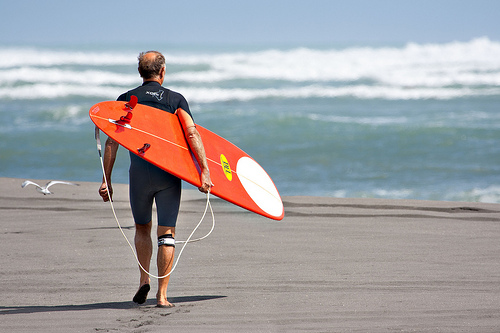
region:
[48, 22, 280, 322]
man carrying a surfboard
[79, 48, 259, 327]
man carrying a surfboard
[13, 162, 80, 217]
the bird is white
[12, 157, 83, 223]
the bird is white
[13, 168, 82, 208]
the bird is white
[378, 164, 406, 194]
Small ripples in the water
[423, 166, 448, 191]
Small ripples in the water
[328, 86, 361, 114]
Small ripples in the water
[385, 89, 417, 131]
Small ripples in the water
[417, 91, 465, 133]
Small ripples in the water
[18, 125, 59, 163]
Small ripples in the water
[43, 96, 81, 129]
Small ripples in the water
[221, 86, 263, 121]
Small ripples in the water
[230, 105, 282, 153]
Small ripples in the water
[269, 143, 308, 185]
Small ripples in the water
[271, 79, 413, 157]
Section of mass water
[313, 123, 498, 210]
Section of mass water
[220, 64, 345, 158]
Section of mass water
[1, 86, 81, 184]
Section of mass water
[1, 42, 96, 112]
Section of mass water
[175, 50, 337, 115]
Section of mass water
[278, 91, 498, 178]
Section of mass water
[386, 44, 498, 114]
Section of mass water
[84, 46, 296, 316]
This is a person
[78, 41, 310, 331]
a person with a surf board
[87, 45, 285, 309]
a man holding a surf board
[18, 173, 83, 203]
a white bird flying over a beach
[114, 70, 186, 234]
a man wearing a wetsuit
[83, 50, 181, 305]
a man walking on a beach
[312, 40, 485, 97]
white waves in the ocean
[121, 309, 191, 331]
foot prints in the sand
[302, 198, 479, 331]
a sandy beach next to the ocean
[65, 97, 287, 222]
a orange surf board with a white circle on it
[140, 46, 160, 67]
a man with a bald spot on his head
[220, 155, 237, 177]
a yellow sticker on a surfboard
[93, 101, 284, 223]
orange and white surfboard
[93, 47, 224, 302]
man wearing wetsuit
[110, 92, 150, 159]
red fins on the surfboard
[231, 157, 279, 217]
white circle on the bottom of the surfboard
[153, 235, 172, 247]
strap around man's leg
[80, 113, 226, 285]
white cord attached to surfboard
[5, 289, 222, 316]
shadow of surfer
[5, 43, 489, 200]
waves crashing in the ocean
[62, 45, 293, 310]
surfer walking towards ocean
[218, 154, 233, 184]
yellow oval on surfboard's bottom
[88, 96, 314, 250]
the surfboard is orange